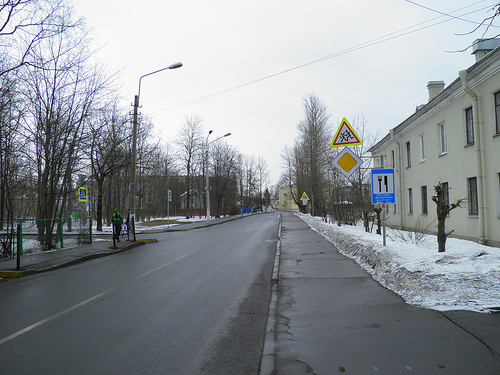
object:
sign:
[371, 169, 396, 206]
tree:
[433, 184, 466, 252]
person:
[111, 208, 121, 243]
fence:
[1, 216, 92, 257]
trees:
[0, 3, 385, 261]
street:
[4, 209, 500, 375]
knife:
[381, 174, 388, 192]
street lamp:
[129, 61, 184, 241]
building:
[364, 37, 499, 245]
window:
[465, 105, 476, 148]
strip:
[0, 213, 275, 348]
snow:
[294, 209, 500, 313]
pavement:
[257, 211, 500, 375]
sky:
[0, 0, 500, 199]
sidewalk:
[1, 236, 146, 277]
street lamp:
[205, 129, 232, 220]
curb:
[135, 238, 159, 245]